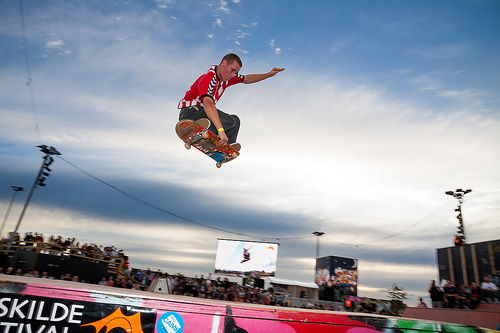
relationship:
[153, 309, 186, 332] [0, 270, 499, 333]
advertisement on wall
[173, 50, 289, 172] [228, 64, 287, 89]
skateboarder has arm